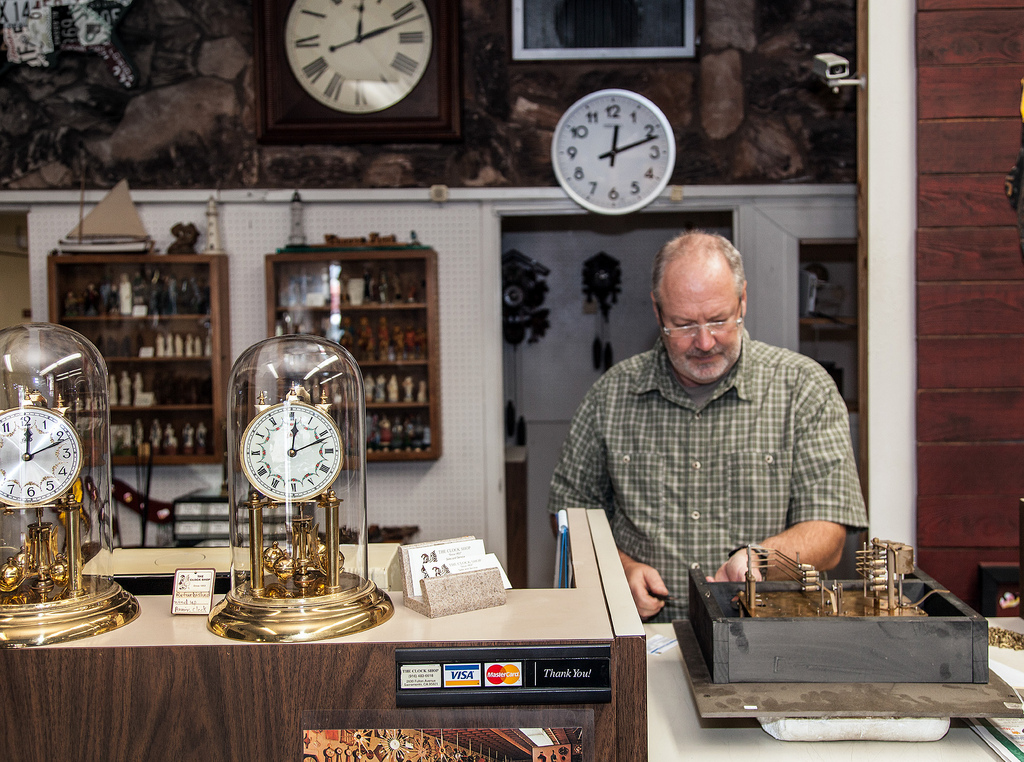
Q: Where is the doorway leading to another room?
A: It is visible behind the man.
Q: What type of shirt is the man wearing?
A: A buttoned-up shirt.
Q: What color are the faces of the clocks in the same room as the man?
A: They are white.